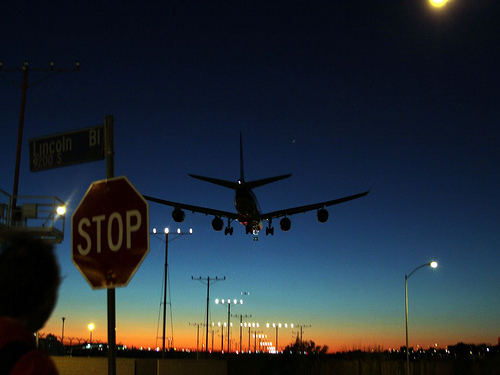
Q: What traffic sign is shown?
A: Stop sign.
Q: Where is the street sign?
A: Above stop sign.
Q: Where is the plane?
A: In air.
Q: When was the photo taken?
A: Sunset.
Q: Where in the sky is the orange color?
A: Bottom.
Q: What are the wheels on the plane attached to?
A: Landing gear.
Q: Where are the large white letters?
A: Red sign.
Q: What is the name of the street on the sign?
A: Lincoln Bl.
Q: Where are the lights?
A: On light poles.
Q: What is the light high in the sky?
A: Moon.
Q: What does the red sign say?
A: Stop.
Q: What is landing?
A: Plane.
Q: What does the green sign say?
A: Lincoln BL.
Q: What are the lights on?
A: Poles.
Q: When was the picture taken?
A: Night.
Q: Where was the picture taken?
A: Airport.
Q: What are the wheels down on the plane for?
A: To land.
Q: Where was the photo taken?
A: Madison.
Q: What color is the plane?
A: White.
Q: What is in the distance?
A: The airport.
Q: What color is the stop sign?
A: Red.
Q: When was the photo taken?
A: Yesterday.